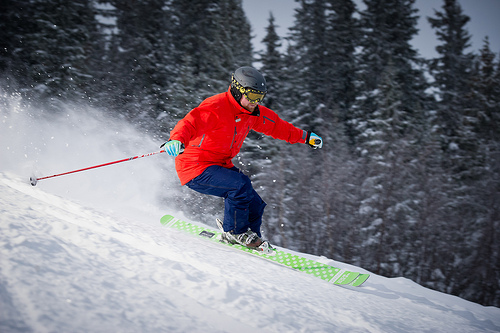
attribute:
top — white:
[137, 136, 161, 157]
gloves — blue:
[155, 135, 184, 158]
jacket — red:
[166, 82, 306, 191]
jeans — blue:
[189, 158, 274, 242]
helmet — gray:
[235, 60, 268, 99]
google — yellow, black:
[228, 69, 266, 104]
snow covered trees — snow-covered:
[4, 3, 497, 309]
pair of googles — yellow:
[301, 127, 324, 151]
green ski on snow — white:
[159, 208, 370, 294]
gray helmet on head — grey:
[230, 63, 267, 114]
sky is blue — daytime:
[468, 3, 500, 27]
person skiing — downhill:
[160, 66, 327, 250]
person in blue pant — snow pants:
[161, 64, 323, 256]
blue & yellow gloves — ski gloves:
[162, 131, 185, 159]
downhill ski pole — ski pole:
[21, 131, 186, 190]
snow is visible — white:
[7, 203, 162, 326]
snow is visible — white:
[144, 230, 201, 332]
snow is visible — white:
[266, 261, 296, 330]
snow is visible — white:
[345, 288, 391, 332]